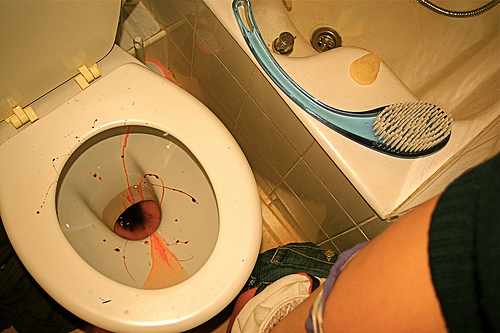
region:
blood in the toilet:
[71, 147, 208, 306]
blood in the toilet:
[106, 190, 176, 265]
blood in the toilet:
[83, 174, 170, 252]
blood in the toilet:
[97, 185, 219, 273]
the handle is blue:
[235, 22, 349, 135]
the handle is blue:
[254, 59, 369, 179]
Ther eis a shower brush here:
[383, 96, 424, 146]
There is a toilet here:
[75, 268, 88, 320]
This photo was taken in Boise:
[55, 293, 89, 323]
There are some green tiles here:
[214, 51, 239, 87]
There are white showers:
[439, 14, 470, 85]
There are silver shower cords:
[453, 5, 464, 30]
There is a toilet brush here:
[126, 29, 146, 54]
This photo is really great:
[86, 18, 224, 327]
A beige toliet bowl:
[8, 12, 253, 319]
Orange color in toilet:
[85, 153, 201, 288]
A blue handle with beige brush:
[247, 16, 445, 161]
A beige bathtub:
[224, 11, 489, 174]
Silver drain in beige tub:
[277, 15, 349, 50]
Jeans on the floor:
[276, 225, 336, 282]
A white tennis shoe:
[233, 269, 316, 331]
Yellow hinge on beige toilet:
[0, 87, 45, 123]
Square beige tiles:
[215, 40, 280, 136]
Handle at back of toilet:
[128, 29, 191, 69]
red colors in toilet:
[104, 165, 189, 252]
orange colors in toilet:
[141, 228, 188, 262]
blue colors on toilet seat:
[51, 116, 108, 161]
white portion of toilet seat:
[227, 183, 254, 248]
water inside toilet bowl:
[110, 190, 147, 237]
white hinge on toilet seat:
[80, 61, 96, 78]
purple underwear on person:
[310, 245, 370, 302]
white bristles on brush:
[380, 101, 466, 152]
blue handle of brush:
[241, 0, 367, 140]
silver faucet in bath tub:
[307, 22, 344, 59]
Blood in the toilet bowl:
[46, 135, 231, 309]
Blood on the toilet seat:
[27, 147, 68, 254]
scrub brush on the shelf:
[274, 64, 456, 168]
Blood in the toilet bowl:
[88, 168, 193, 275]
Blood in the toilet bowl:
[91, 165, 105, 185]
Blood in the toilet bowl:
[103, 236, 123, 257]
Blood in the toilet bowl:
[141, 171, 165, 192]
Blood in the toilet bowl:
[179, 185, 199, 217]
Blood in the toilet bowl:
[119, 232, 196, 267]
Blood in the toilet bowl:
[116, 196, 151, 233]